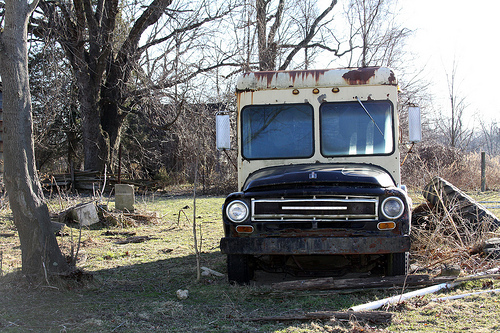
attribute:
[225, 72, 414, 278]
truck — rusty, parked, old, rusted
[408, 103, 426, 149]
mirror — sideview, white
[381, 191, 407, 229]
headlight — round, white, yellow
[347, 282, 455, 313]
pole — metal, gray, long, white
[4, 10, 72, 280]
tree trunk — gray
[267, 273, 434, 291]
log — tall, brown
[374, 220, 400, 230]
light — oval, small, yellow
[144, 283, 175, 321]
grass — green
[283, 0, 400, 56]
branches — bare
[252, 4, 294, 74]
tree — brown, tall, dark, thick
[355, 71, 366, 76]
metal — rusted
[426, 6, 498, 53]
sky — sunlight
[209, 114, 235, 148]
mirror — sideview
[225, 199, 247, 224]
headlight — white, yellow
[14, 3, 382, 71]
trees — bare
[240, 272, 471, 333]
articles — discarded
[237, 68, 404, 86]
top — rusted